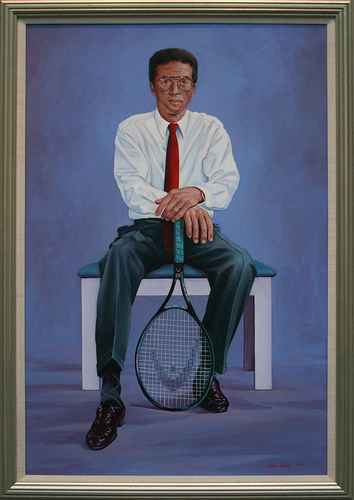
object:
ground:
[249, 398, 331, 429]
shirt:
[113, 107, 241, 220]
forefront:
[24, 192, 327, 474]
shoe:
[85, 397, 126, 451]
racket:
[134, 219, 215, 412]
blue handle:
[173, 219, 184, 262]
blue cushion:
[75, 255, 277, 278]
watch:
[195, 186, 207, 204]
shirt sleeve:
[194, 129, 241, 208]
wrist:
[192, 183, 211, 206]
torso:
[113, 109, 240, 218]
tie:
[163, 124, 180, 255]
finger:
[161, 201, 176, 221]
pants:
[95, 217, 256, 374]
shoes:
[191, 368, 231, 414]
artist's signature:
[266, 460, 304, 468]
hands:
[185, 202, 215, 245]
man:
[83, 46, 257, 449]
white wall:
[39, 47, 300, 245]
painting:
[24, 21, 329, 478]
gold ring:
[175, 201, 181, 210]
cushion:
[77, 250, 277, 279]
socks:
[98, 369, 125, 411]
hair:
[148, 48, 197, 84]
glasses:
[153, 75, 195, 92]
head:
[135, 308, 214, 410]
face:
[156, 63, 193, 113]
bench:
[76, 260, 277, 391]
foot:
[85, 394, 127, 450]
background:
[27, 27, 314, 387]